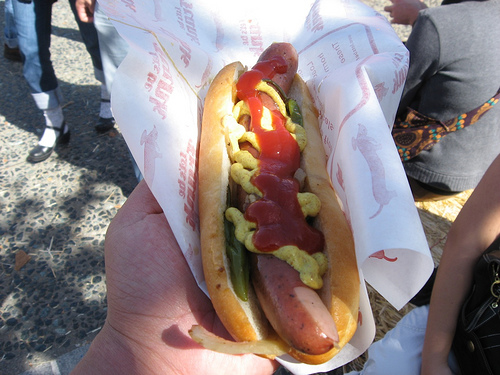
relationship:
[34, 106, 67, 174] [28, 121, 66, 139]
shoe with strap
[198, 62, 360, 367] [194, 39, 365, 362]
bun of hotdog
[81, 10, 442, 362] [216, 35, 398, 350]
paper around hotdog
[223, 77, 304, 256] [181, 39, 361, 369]
ketchup on hot dog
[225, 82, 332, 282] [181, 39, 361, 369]
mustard on hot dog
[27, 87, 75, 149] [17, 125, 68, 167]
sock in shoe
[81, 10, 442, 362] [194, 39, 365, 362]
paper under hotdog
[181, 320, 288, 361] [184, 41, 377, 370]
onion under hot dog